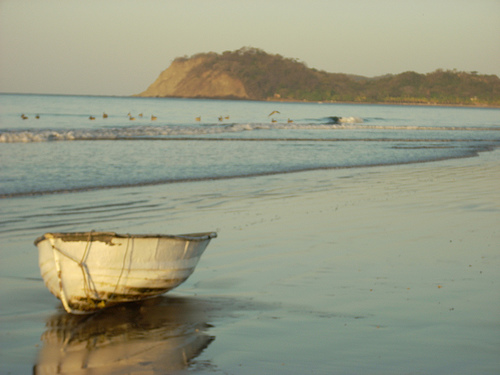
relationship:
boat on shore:
[35, 219, 220, 315] [0, 149, 498, 374]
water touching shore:
[1, 91, 499, 195] [0, 149, 498, 374]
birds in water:
[17, 107, 298, 129] [1, 91, 499, 195]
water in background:
[1, 91, 499, 195] [1, 1, 498, 199]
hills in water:
[137, 48, 499, 104] [1, 91, 499, 195]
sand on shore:
[0, 155, 496, 374] [0, 149, 498, 374]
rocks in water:
[137, 48, 499, 104] [1, 91, 499, 195]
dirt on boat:
[75, 284, 169, 305] [35, 219, 220, 315]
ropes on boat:
[55, 233, 97, 300] [35, 219, 220, 315]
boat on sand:
[35, 219, 220, 315] [0, 155, 496, 374]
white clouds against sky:
[1, 0, 497, 94] [2, 0, 499, 50]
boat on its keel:
[35, 219, 220, 315] [63, 298, 157, 310]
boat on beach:
[35, 219, 220, 315] [0, 149, 498, 374]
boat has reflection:
[35, 219, 220, 315] [30, 306, 212, 373]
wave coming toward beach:
[1, 127, 282, 141] [0, 149, 498, 374]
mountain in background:
[137, 48, 499, 104] [1, 1, 498, 199]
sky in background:
[2, 0, 499, 95] [1, 1, 498, 199]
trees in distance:
[437, 66, 483, 76] [1, 1, 498, 199]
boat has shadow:
[35, 219, 220, 315] [45, 298, 272, 321]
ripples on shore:
[19, 198, 175, 227] [0, 149, 498, 374]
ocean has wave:
[1, 91, 499, 195] [1, 122, 499, 140]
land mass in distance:
[137, 48, 499, 104] [1, 1, 498, 199]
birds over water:
[17, 107, 298, 129] [1, 91, 499, 195]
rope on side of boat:
[55, 233, 97, 300] [35, 219, 220, 315]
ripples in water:
[19, 198, 175, 227] [1, 91, 499, 195]